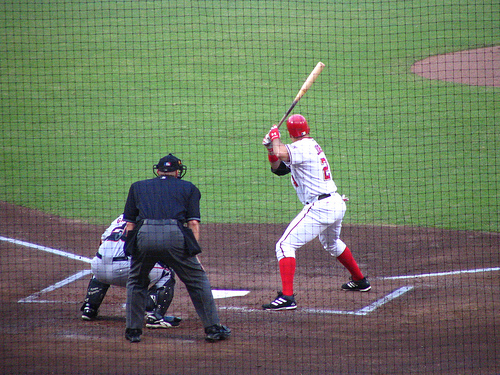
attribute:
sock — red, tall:
[275, 255, 297, 296]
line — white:
[2, 230, 95, 269]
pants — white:
[274, 197, 348, 263]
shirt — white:
[285, 137, 340, 203]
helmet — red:
[284, 113, 313, 140]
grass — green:
[3, 3, 500, 230]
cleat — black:
[366, 287, 374, 295]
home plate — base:
[211, 285, 252, 304]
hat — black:
[152, 153, 184, 173]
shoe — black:
[261, 294, 299, 314]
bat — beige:
[261, 60, 327, 148]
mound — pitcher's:
[407, 39, 499, 94]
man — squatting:
[77, 209, 184, 331]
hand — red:
[267, 119, 280, 137]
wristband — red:
[267, 151, 280, 164]